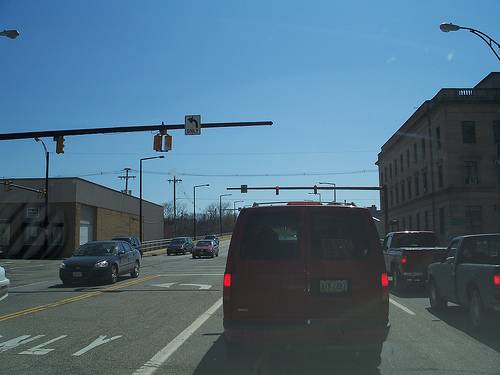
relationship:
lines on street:
[1, 270, 238, 372] [34, 277, 189, 374]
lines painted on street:
[1, 270, 238, 372] [6, 137, 333, 373]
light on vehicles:
[381, 273, 387, 285] [207, 193, 392, 355]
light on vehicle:
[223, 273, 231, 283] [222, 204, 389, 354]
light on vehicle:
[380, 272, 388, 286] [222, 204, 389, 354]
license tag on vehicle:
[318, 279, 348, 295] [222, 204, 389, 354]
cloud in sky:
[0, 11, 499, 177] [91, 22, 398, 96]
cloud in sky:
[0, 11, 499, 177] [0, 1, 497, 216]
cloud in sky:
[446, 48, 454, 61] [0, 1, 497, 216]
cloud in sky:
[0, 11, 499, 177] [300, 99, 335, 153]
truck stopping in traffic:
[424, 232, 499, 327] [55, 193, 485, 370]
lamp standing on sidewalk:
[124, 141, 199, 256] [135, 230, 180, 261]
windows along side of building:
[403, 150, 446, 185] [347, 76, 469, 233]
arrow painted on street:
[151, 280, 212, 291] [65, 265, 221, 355]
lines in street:
[1, 270, 238, 372] [48, 274, 218, 368]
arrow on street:
[151, 281, 212, 289] [37, 272, 223, 367]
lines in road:
[1, 267, 238, 372] [2, 239, 497, 374]